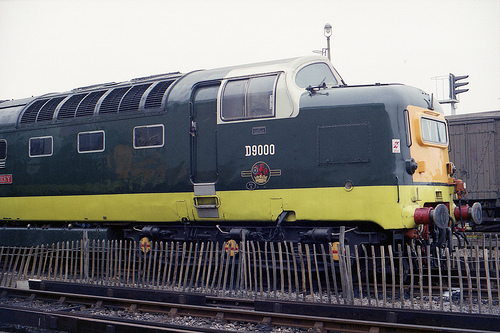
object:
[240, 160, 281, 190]
logo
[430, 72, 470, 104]
cage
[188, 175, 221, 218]
step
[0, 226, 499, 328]
fence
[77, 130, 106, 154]
window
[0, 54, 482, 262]
car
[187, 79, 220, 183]
door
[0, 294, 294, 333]
gravel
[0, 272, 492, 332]
track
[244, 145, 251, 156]
letter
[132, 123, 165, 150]
window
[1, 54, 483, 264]
train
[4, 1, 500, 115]
sky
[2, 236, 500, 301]
tracks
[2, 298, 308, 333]
rocks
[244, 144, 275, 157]
number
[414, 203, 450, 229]
bumper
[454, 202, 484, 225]
bumper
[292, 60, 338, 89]
windshield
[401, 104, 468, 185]
front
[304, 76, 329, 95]
wiper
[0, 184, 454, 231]
stripe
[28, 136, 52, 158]
windows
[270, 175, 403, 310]
no object